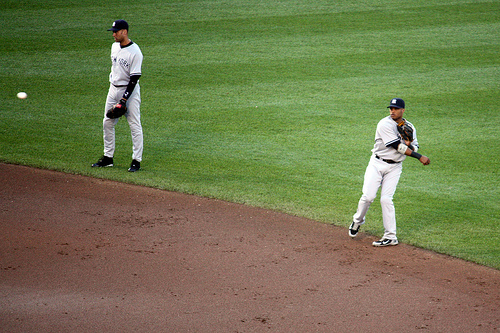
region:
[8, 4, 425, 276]
two men are on the playing field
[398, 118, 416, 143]
the man wears a baseball glove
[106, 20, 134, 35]
the man wears a baseball cap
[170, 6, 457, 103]
this portion of the field is covered in grass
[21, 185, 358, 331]
this portion of the playing field is covered in dirt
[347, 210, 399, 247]
the mans cleats are black and white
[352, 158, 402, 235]
the man wears white playing pants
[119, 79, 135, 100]
the man is wearing a long sleeve black shirt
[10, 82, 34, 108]
the baseball is in the air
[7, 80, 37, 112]
the baseball has been thrown and is in motion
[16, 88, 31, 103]
white baseball in the air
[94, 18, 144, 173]
baseball player standing in wait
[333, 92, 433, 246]
baseball playing following through with a throw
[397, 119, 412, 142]
a black baseball glove on the players hand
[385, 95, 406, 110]
blue baseball hat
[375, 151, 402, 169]
black belt on the white pants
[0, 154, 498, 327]
dirt section of the field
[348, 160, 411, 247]
white pants of the baseball uniform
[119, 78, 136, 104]
black sleeve of an undershirt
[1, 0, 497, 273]
green grass on the baseball field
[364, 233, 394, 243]
part of a shoe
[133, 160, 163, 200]
part of a shoe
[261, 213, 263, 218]
edge of a lawn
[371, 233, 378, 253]
part of a shoe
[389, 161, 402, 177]
part of a trouser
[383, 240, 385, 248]
edge of a shoe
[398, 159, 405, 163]
part of a belt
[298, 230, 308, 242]
part of a grass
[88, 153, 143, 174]
black cleats on the player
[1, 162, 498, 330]
brown dirt on the field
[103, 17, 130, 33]
black hat on the player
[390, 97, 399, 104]
white logo on the black hat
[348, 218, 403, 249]
white and black cleats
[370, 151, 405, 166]
black belt in the player's pants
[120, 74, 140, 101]
black long sleeve under the jersey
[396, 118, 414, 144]
black glove on the player's hand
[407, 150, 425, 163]
black wristband on the player's arm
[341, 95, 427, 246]
baseball player in white uniform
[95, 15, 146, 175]
baseball player in navy blue hat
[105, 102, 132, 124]
black leather catching mitt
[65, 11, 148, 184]
a man standing on grass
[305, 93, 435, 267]
a man swinging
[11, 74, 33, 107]
a ball in air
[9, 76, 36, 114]
the ball is white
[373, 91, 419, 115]
a blue ball cap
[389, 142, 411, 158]
a white band on arm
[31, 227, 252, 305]
brown dirt on ground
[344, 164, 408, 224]
a white pair of pants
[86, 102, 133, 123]
a hand holding a mitt